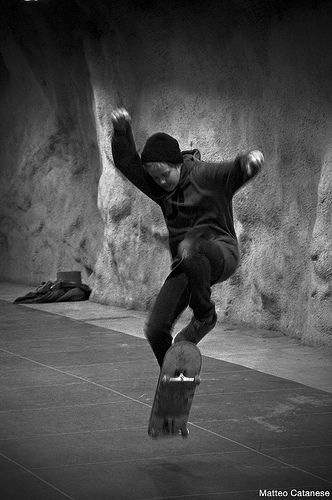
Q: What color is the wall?
A: Gray.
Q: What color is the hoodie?
A: Black.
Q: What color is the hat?
A: Black.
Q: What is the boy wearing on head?
A: A black hat.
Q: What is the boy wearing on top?
A: A hooded shirt.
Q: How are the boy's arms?
A: Stretched.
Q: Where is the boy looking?
A: Down.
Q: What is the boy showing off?
A: Skateboard trick in air.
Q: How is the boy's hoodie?
A: Black graphic.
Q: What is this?
A: Rugged inside of cave.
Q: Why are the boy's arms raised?
A: He is balancing.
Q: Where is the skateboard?
A: In mid-air.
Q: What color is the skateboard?
A: Brown.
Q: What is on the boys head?
A: Cap.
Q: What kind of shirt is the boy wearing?
A: A sweatshirt.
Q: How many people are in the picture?
A: One.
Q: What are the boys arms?
A: In the air.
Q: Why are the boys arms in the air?
A: Balance.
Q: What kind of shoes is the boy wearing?
A: Sneakers.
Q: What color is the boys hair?
A: Blonde.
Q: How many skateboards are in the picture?
A: One.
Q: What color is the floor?
A: Gray.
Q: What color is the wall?
A: Gray.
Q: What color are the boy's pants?
A: Gray.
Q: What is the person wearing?
A: A hat.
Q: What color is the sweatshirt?
A: Black.